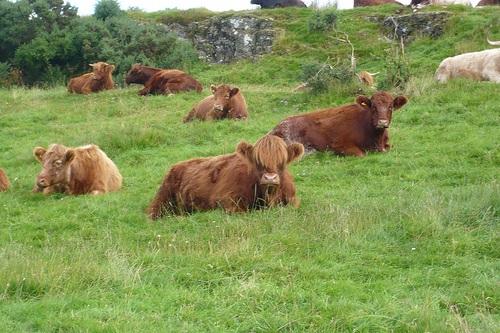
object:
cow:
[144, 133, 305, 222]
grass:
[0, 7, 500, 333]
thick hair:
[247, 134, 289, 177]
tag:
[361, 102, 366, 105]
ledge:
[191, 5, 500, 87]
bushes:
[11, 20, 113, 90]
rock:
[371, 12, 452, 43]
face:
[250, 146, 287, 188]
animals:
[31, 142, 124, 197]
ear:
[286, 142, 305, 165]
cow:
[432, 23, 500, 85]